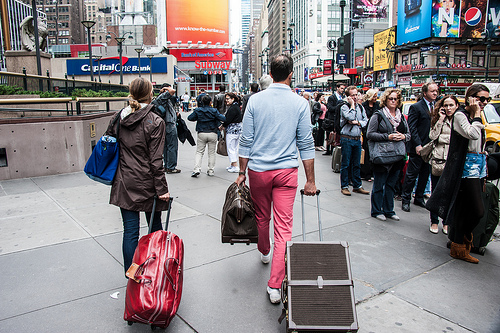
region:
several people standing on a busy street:
[324, 8, 499, 332]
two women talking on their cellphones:
[439, 78, 497, 263]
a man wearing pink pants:
[226, 53, 328, 306]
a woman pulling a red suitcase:
[90, 74, 177, 328]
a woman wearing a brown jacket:
[102, 70, 176, 217]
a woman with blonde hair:
[122, 68, 154, 116]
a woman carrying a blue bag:
[81, 76, 178, 190]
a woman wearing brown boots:
[443, 78, 497, 267]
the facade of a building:
[265, 0, 287, 55]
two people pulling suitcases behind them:
[84, 45, 379, 328]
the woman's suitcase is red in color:
[89, 76, 183, 319]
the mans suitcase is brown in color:
[225, 57, 362, 329]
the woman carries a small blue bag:
[83, 74, 171, 188]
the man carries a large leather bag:
[213, 34, 312, 244]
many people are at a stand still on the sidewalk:
[324, 69, 493, 271]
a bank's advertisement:
[63, 52, 170, 77]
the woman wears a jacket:
[100, 108, 172, 218]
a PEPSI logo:
[457, 5, 486, 36]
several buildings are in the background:
[13, 4, 477, 94]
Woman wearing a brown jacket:
[102, 76, 176, 284]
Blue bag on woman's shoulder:
[76, 104, 139, 186]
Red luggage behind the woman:
[115, 188, 193, 328]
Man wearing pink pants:
[230, 51, 322, 309]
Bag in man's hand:
[211, 168, 257, 247]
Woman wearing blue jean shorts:
[428, 80, 498, 264]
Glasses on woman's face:
[469, 90, 494, 104]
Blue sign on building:
[57, 53, 172, 87]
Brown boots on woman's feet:
[438, 226, 479, 268]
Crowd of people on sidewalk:
[290, 74, 498, 274]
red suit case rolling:
[113, 191, 198, 326]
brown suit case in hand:
[211, 172, 263, 250]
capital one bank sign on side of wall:
[65, 37, 170, 81]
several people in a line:
[323, 78, 483, 246]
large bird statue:
[10, 13, 56, 58]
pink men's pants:
[233, 158, 310, 303]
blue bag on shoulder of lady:
[87, 105, 134, 185]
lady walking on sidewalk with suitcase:
[68, 55, 198, 329]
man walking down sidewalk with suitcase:
[212, 47, 374, 332]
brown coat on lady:
[91, 101, 178, 213]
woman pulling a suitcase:
[76, 61, 236, 321]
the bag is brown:
[194, 157, 271, 270]